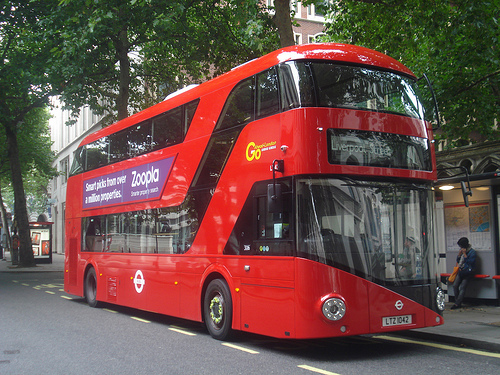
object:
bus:
[64, 44, 444, 341]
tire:
[204, 278, 239, 340]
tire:
[84, 267, 105, 307]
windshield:
[295, 176, 436, 283]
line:
[296, 363, 341, 375]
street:
[0, 270, 498, 374]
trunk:
[4, 126, 38, 266]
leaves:
[0, 0, 58, 119]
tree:
[1, 0, 58, 269]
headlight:
[322, 297, 346, 321]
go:
[245, 142, 261, 162]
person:
[452, 237, 477, 309]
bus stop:
[433, 172, 500, 299]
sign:
[81, 153, 178, 210]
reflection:
[391, 74, 426, 119]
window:
[308, 59, 426, 121]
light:
[439, 185, 455, 191]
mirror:
[267, 183, 284, 212]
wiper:
[326, 179, 433, 193]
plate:
[382, 315, 412, 327]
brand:
[133, 270, 145, 294]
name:
[332, 140, 363, 155]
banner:
[29, 228, 50, 259]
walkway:
[414, 299, 497, 349]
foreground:
[0, 264, 500, 373]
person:
[0, 233, 8, 261]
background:
[1, 0, 500, 341]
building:
[51, 0, 335, 253]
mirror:
[434, 202, 447, 290]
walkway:
[0, 252, 65, 273]